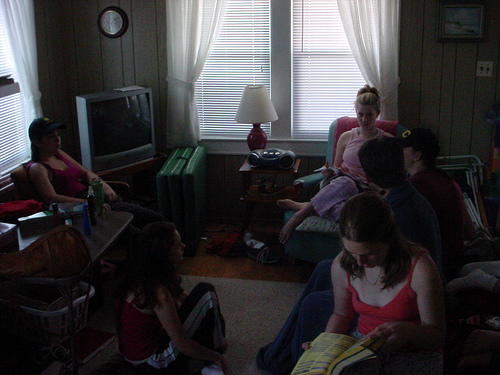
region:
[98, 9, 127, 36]
a clock on the wall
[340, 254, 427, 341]
a red tank top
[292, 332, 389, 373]
a yellow pages phone book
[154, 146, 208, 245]
green folded tables against the wall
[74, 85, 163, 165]
a box television set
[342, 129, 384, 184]
a pink pajama top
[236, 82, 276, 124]
a white lamp shade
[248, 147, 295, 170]
a black table top stereo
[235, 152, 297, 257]
a brown side table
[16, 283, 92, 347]
a white plastic basket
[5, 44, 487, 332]
many people in room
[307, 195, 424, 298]
head of a lady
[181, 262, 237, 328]
knee of the girl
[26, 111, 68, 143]
hat on lady's head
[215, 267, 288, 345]
carpet on the ground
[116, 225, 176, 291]
hair on the girl's head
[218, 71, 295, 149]
lamp next to the girl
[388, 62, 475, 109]
lines on the wall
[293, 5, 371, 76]
window behind the girl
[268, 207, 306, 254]
foot of the girl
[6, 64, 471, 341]
many people in photo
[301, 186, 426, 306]
head of the girl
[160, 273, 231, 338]
knee of the girl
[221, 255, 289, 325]
carpet next to people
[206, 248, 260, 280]
wood floor under people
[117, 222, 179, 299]
hair on girl's head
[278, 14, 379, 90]
window behind the lady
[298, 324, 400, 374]
book in girl's hand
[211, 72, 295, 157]
lamp on the table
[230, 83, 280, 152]
Lamp on a table.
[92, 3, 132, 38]
Clock on a wall.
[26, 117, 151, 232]
Woman sitting on a chair.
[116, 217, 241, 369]
Female sitting on the floor.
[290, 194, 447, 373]
Woman looking at a book.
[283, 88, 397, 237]
Female wearing a pink shirt.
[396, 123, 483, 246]
Man wearing a ball cap.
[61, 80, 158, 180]
Television in a corner.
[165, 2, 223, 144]
White curtain on the window.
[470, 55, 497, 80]
Light switch on a wall.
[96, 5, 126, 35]
a round clock hanging on the wall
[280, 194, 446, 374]
a woman looking through a phone book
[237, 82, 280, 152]
a lamp with a white lamp shade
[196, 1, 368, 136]
window blinds covering the window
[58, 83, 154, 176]
a TV with a silver housing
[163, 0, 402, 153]
sheer white curtains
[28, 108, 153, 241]
a woman wearing a black cap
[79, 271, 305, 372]
a tan colored rug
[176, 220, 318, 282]
a hardwood floor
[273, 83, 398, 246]
a woman wearing a pink shirt